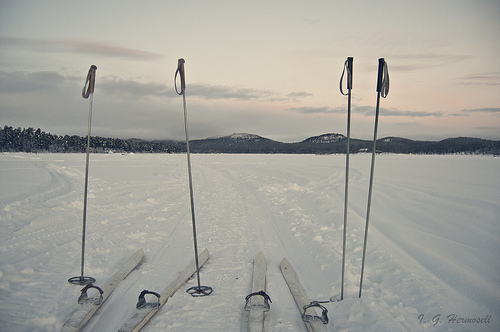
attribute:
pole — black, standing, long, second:
[165, 52, 223, 301]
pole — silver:
[334, 55, 358, 306]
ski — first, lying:
[51, 243, 150, 331]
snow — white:
[51, 186, 430, 331]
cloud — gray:
[101, 65, 171, 110]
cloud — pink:
[219, 97, 338, 118]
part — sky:
[175, 1, 462, 36]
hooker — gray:
[338, 49, 357, 105]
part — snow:
[118, 161, 178, 217]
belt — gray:
[77, 62, 106, 104]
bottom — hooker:
[183, 282, 219, 301]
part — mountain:
[205, 127, 282, 154]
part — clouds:
[213, 74, 341, 123]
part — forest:
[9, 124, 76, 156]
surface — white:
[206, 166, 339, 224]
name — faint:
[414, 311, 497, 328]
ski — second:
[117, 241, 213, 331]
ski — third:
[241, 248, 273, 331]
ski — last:
[278, 256, 332, 331]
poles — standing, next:
[335, 53, 392, 304]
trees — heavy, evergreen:
[0, 126, 85, 154]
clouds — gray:
[4, 69, 74, 120]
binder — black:
[125, 287, 170, 312]